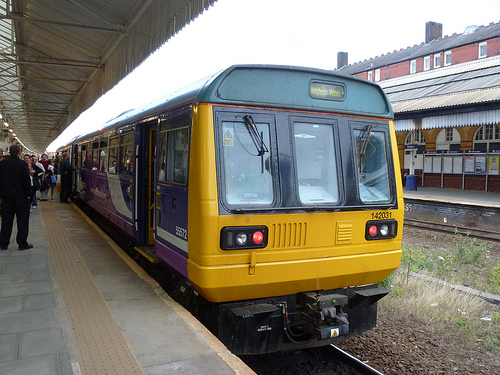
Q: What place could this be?
A: It is a station.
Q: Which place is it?
A: It is a station.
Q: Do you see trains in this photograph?
A: Yes, there is a train.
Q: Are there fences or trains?
A: Yes, there is a train.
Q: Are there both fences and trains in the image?
A: No, there is a train but no fences.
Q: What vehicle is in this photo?
A: The vehicle is a train.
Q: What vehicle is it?
A: The vehicle is a train.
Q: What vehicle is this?
A: This is a train.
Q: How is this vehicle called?
A: This is a train.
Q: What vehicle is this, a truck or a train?
A: This is a train.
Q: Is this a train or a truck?
A: This is a train.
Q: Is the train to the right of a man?
A: Yes, the train is to the right of a man.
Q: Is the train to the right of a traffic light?
A: No, the train is to the right of a man.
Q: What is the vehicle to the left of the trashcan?
A: The vehicle is a train.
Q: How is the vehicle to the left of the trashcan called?
A: The vehicle is a train.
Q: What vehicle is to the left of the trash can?
A: The vehicle is a train.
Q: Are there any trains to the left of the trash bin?
A: Yes, there is a train to the left of the trash bin.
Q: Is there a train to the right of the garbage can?
A: No, the train is to the left of the garbage can.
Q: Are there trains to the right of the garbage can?
A: No, the train is to the left of the garbage can.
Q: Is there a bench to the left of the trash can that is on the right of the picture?
A: No, there is a train to the left of the garbage can.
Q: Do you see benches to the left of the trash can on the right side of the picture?
A: No, there is a train to the left of the garbage can.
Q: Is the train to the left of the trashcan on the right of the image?
A: Yes, the train is to the left of the trashcan.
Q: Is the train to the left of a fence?
A: No, the train is to the left of the trashcan.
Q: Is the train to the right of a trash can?
A: No, the train is to the left of a trash can.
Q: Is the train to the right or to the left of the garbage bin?
A: The train is to the left of the garbage bin.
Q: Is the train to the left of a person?
A: No, the train is to the right of a person.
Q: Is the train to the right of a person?
A: Yes, the train is to the right of a person.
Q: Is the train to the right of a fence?
A: No, the train is to the right of a person.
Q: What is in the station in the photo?
A: The train is in the station.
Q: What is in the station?
A: The train is in the station.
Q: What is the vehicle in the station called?
A: The vehicle is a train.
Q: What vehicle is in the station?
A: The vehicle is a train.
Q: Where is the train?
A: The train is in the station.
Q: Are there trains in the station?
A: Yes, there is a train in the station.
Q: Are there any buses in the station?
A: No, there is a train in the station.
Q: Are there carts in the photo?
A: No, there are no carts.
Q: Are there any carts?
A: No, there are no carts.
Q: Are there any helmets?
A: No, there are no helmets.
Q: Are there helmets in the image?
A: No, there are no helmets.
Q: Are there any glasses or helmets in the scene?
A: No, there are no helmets or glasses.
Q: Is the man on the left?
A: Yes, the man is on the left of the image.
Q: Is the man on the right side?
A: No, the man is on the left of the image.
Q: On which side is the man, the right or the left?
A: The man is on the left of the image.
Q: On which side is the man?
A: The man is on the left of the image.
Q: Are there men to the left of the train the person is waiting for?
A: Yes, there is a man to the left of the train.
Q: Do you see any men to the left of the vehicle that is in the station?
A: Yes, there is a man to the left of the train.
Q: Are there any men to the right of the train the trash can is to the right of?
A: No, the man is to the left of the train.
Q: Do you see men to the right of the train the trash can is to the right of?
A: No, the man is to the left of the train.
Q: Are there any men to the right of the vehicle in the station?
A: No, the man is to the left of the train.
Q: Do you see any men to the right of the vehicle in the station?
A: No, the man is to the left of the train.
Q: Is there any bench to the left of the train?
A: No, there is a man to the left of the train.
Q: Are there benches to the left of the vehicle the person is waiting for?
A: No, there is a man to the left of the train.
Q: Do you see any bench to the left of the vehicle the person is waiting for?
A: No, there is a man to the left of the train.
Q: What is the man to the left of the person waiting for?
A: The man is waiting for the train.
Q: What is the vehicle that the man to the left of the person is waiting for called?
A: The vehicle is a train.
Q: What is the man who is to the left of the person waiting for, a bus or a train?
A: The man is waiting for a train.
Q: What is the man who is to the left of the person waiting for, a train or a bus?
A: The man is waiting for a train.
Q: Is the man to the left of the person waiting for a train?
A: Yes, the man is waiting for a train.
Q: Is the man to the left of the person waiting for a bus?
A: No, the man is waiting for a train.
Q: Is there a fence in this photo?
A: No, there are no fences.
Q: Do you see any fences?
A: No, there are no fences.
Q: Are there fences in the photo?
A: No, there are no fences.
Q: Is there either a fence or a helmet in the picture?
A: No, there are no fences or helmets.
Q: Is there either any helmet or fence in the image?
A: No, there are no fences or helmets.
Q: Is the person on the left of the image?
A: Yes, the person is on the left of the image.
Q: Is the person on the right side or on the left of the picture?
A: The person is on the left of the image.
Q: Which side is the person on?
A: The person is on the left of the image.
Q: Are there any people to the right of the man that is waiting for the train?
A: Yes, there is a person to the right of the man.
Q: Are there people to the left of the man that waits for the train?
A: No, the person is to the right of the man.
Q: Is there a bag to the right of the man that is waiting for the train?
A: No, there is a person to the right of the man.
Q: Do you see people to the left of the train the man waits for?
A: Yes, there is a person to the left of the train.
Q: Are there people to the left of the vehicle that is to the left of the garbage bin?
A: Yes, there is a person to the left of the train.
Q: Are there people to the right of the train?
A: No, the person is to the left of the train.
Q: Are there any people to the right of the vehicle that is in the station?
A: No, the person is to the left of the train.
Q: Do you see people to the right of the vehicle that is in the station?
A: No, the person is to the left of the train.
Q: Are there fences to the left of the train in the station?
A: No, there is a person to the left of the train.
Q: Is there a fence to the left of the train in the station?
A: No, there is a person to the left of the train.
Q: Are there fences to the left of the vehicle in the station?
A: No, there is a person to the left of the train.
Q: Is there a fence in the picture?
A: No, there are no fences.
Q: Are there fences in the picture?
A: No, there are no fences.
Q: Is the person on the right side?
A: No, the person is on the left of the image.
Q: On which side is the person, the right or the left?
A: The person is on the left of the image.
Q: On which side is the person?
A: The person is on the left of the image.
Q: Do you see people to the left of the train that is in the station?
A: Yes, there is a person to the left of the train.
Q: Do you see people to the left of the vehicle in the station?
A: Yes, there is a person to the left of the train.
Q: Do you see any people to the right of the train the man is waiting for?
A: No, the person is to the left of the train.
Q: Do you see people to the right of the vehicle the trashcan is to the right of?
A: No, the person is to the left of the train.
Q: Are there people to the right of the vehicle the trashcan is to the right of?
A: No, the person is to the left of the train.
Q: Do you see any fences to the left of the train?
A: No, there is a person to the left of the train.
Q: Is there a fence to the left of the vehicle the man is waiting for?
A: No, there is a person to the left of the train.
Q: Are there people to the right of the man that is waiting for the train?
A: Yes, there is a person to the right of the man.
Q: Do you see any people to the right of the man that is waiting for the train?
A: Yes, there is a person to the right of the man.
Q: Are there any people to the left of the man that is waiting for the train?
A: No, the person is to the right of the man.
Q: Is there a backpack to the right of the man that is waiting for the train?
A: No, there is a person to the right of the man.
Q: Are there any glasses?
A: No, there are no glasses.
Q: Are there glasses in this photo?
A: No, there are no glasses.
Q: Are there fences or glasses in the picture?
A: No, there are no glasses or fences.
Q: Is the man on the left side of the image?
A: Yes, the man is on the left of the image.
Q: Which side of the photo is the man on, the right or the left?
A: The man is on the left of the image.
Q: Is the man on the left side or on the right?
A: The man is on the left of the image.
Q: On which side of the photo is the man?
A: The man is on the left of the image.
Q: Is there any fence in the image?
A: No, there are no fences.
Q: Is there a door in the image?
A: Yes, there is a door.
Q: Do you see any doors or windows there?
A: Yes, there is a door.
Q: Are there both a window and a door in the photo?
A: Yes, there are both a door and a window.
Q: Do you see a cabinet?
A: No, there are no cabinets.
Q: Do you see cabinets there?
A: No, there are no cabinets.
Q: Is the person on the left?
A: Yes, the person is on the left of the image.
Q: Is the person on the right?
A: No, the person is on the left of the image.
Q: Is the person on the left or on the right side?
A: The person is on the left of the image.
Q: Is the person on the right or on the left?
A: The person is on the left of the image.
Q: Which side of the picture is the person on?
A: The person is on the left of the image.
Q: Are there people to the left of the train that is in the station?
A: Yes, there is a person to the left of the train.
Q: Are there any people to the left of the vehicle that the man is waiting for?
A: Yes, there is a person to the left of the train.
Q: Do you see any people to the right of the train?
A: No, the person is to the left of the train.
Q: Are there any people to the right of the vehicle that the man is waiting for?
A: No, the person is to the left of the train.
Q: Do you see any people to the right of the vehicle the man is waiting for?
A: No, the person is to the left of the train.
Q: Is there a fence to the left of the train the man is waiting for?
A: No, there is a person to the left of the train.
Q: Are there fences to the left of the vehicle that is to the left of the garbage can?
A: No, there is a person to the left of the train.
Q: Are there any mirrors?
A: No, there are no mirrors.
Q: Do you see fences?
A: No, there are no fences.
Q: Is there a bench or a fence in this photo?
A: No, there are no fences or benches.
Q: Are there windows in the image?
A: Yes, there are windows.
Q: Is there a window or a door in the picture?
A: Yes, there are windows.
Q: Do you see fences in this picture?
A: No, there are no fences.